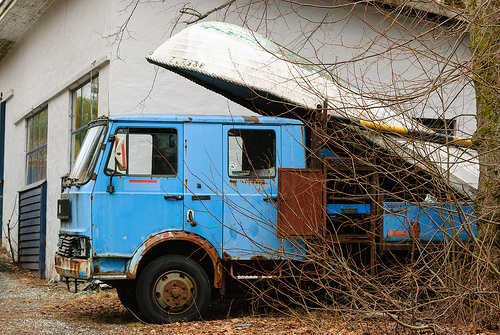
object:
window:
[226, 127, 277, 179]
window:
[61, 123, 106, 188]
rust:
[126, 229, 224, 288]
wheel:
[134, 253, 211, 325]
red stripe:
[128, 179, 157, 183]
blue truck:
[54, 112, 479, 324]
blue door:
[91, 122, 187, 258]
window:
[102, 126, 179, 178]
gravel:
[27, 321, 38, 328]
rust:
[275, 167, 323, 241]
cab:
[53, 115, 226, 322]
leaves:
[229, 318, 243, 324]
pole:
[324, 113, 478, 151]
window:
[22, 99, 48, 186]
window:
[66, 69, 102, 175]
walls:
[109, 0, 481, 186]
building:
[0, 2, 482, 292]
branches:
[234, 1, 468, 67]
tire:
[122, 252, 218, 325]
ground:
[0, 268, 500, 335]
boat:
[145, 19, 478, 200]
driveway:
[0, 267, 102, 335]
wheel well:
[127, 229, 225, 290]